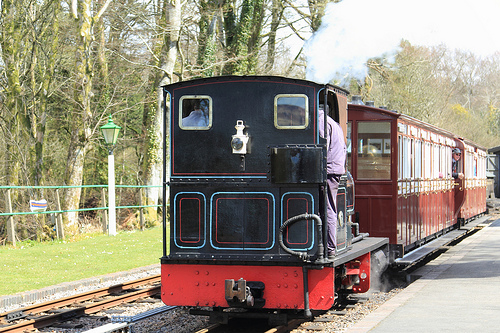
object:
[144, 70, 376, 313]
train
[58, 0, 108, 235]
tree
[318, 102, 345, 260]
man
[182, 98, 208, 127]
man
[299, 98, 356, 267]
man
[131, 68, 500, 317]
train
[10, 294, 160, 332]
tracks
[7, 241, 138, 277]
grass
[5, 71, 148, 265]
background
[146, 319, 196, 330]
gravel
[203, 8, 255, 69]
tree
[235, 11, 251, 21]
leaves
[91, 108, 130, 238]
lamp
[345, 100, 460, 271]
cars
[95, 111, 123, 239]
post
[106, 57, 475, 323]
closest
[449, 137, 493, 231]
car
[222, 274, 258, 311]
hitch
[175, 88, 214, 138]
window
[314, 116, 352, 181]
back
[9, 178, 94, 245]
fence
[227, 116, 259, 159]
light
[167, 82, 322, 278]
front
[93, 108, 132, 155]
lamp